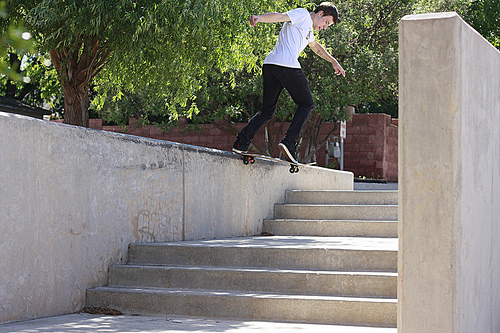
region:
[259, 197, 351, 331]
this is a staircase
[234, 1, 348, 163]
the man is skating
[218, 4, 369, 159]
the man is on air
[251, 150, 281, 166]
this is a skate board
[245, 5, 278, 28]
the hand is behind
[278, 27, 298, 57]
the t shirt is white in color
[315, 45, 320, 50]
the man is light skinned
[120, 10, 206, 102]
the tree is leafy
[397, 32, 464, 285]
the wall is made of stone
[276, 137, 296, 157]
this is the leg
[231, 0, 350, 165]
young man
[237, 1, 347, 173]
young man on a skateboard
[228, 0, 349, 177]
young man wearing a white shirt and black pants on a skateboard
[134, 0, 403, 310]
young man skating on a ledge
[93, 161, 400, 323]
stairs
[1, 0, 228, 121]
healthy green tree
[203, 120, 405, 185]
red brick wall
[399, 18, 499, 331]
gray wall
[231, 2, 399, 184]
young man on skateboard in front of green trees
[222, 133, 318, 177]
four wheels on skateboard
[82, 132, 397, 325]
light gray concrete steps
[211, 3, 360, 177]
young man skateboarding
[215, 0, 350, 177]
he is jumping off the wall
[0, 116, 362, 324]
cracked gray concrete wall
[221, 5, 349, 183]
he is wearing a white T-Shirt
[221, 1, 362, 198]
he is wearing black pants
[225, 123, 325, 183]
black shoes on his feet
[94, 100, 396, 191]
a red brick wall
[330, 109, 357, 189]
white sign with red lettering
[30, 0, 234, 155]
leafy green tree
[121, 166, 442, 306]
The stairs are concrete.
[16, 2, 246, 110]
The tree is leafy.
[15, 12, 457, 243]
The man is skateboarding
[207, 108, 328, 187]
He is wearing black shoes.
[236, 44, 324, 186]
He is wearing black pants.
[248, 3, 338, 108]
The man is is wearing a white shirt.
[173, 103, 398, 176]
The wall is brick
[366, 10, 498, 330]
The wall is grey concrete.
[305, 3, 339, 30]
He has brown hair.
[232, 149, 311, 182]
The wheels are black.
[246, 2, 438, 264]
the man is skating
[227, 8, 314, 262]
the man is skating